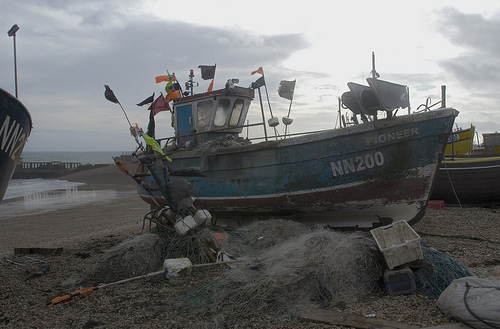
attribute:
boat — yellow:
[444, 126, 474, 162]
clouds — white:
[37, 15, 364, 148]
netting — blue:
[421, 249, 446, 284]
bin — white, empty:
[368, 219, 423, 269]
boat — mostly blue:
[137, 86, 459, 228]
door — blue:
[170, 99, 201, 140]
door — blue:
[171, 103, 198, 147]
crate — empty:
[367, 220, 425, 267]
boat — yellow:
[440, 122, 478, 157]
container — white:
[368, 215, 424, 269]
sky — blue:
[3, 2, 484, 152]